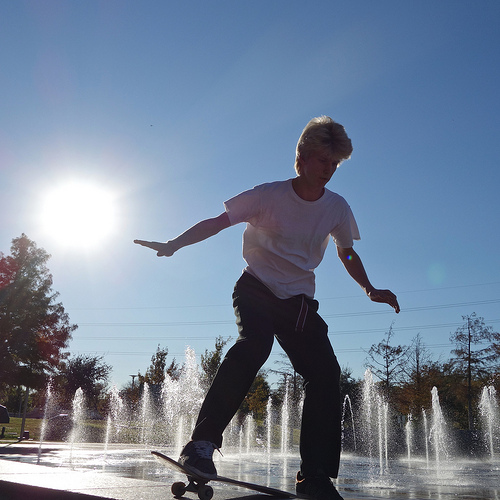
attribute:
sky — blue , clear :
[2, 0, 490, 396]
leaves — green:
[0, 250, 67, 386]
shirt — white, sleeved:
[224, 164, 362, 304]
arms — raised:
[128, 185, 408, 321]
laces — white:
[192, 445, 219, 468]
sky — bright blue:
[6, 4, 495, 351]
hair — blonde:
[293, 113, 354, 158]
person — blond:
[124, 105, 413, 497]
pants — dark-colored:
[181, 267, 355, 485]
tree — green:
[4, 220, 76, 421]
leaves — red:
[37, 278, 51, 298]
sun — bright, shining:
[33, 171, 123, 252]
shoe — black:
[173, 438, 218, 479]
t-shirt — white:
[222, 174, 363, 301]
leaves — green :
[12, 270, 65, 363]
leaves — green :
[58, 363, 94, 389]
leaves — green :
[86, 374, 109, 403]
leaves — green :
[199, 339, 224, 373]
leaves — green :
[270, 371, 294, 392]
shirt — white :
[224, 180, 376, 284]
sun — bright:
[45, 183, 125, 248]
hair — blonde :
[291, 109, 359, 161]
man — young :
[145, 100, 400, 497]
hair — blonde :
[295, 111, 352, 171]